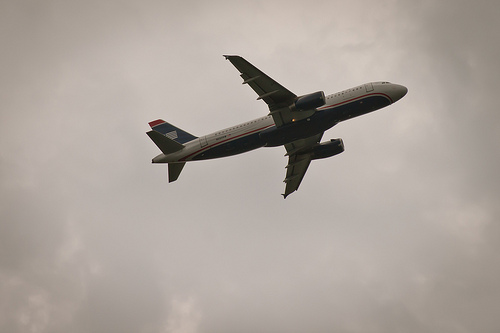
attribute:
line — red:
[195, 84, 383, 152]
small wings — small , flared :
[145, 129, 185, 182]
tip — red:
[145, 115, 165, 128]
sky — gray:
[113, 32, 158, 56]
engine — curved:
[290, 91, 326, 111]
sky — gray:
[0, 0, 499, 331]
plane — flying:
[146, 56, 408, 197]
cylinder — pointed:
[254, 123, 284, 138]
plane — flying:
[143, 49, 409, 204]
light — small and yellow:
[282, 106, 302, 219]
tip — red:
[143, 110, 172, 130]